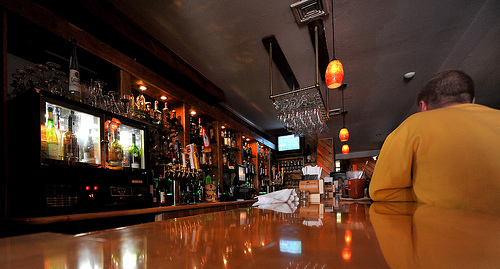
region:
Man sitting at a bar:
[288, 57, 488, 239]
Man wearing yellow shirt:
[367, 69, 497, 232]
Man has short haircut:
[417, 54, 492, 120]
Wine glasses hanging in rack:
[268, 77, 337, 137]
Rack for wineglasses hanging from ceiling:
[257, 10, 331, 143]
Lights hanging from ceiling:
[315, 17, 353, 162]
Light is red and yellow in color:
[316, 55, 350, 92]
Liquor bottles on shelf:
[208, 108, 260, 180]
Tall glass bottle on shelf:
[56, 32, 84, 102]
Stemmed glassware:
[8, 46, 61, 90]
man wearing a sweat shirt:
[362, 66, 497, 189]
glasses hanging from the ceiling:
[246, 20, 332, 135]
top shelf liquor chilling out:
[25, 85, 165, 175]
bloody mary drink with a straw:
[341, 157, 366, 197]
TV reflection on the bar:
[265, 230, 315, 255]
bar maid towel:
[250, 185, 295, 205]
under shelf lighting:
[127, 70, 172, 101]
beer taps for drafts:
[150, 135, 205, 207]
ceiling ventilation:
[285, 0, 340, 25]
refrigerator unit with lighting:
[7, 81, 158, 212]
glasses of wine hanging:
[273, 87, 328, 137]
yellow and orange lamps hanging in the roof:
[322, 9, 353, 165]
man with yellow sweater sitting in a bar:
[369, 67, 497, 204]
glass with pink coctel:
[347, 170, 364, 201]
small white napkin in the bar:
[255, 187, 297, 204]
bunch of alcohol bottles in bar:
[12, 44, 274, 201]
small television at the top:
[270, 129, 301, 151]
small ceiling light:
[402, 69, 417, 83]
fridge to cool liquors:
[15, 97, 147, 208]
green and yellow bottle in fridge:
[42, 104, 60, 160]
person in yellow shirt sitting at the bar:
[354, 68, 496, 231]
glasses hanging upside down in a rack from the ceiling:
[271, 85, 331, 142]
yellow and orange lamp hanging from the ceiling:
[317, 0, 349, 97]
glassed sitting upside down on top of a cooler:
[4, 60, 71, 95]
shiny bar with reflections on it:
[159, 215, 320, 265]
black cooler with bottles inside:
[39, 91, 156, 220]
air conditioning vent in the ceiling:
[288, 0, 330, 27]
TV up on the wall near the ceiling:
[276, 134, 303, 154]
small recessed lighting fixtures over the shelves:
[125, 78, 178, 108]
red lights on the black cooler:
[77, 178, 102, 193]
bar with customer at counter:
[36, 30, 492, 255]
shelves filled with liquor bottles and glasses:
[6, 25, 268, 210]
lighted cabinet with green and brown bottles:
[37, 95, 144, 170]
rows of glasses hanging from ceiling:
[257, 20, 327, 135]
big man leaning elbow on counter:
[360, 46, 495, 206]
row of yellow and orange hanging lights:
[322, 6, 347, 158]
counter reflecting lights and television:
[52, 200, 369, 262]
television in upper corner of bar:
[271, 125, 301, 150]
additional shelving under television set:
[276, 150, 302, 190]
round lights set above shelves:
[128, 72, 260, 142]